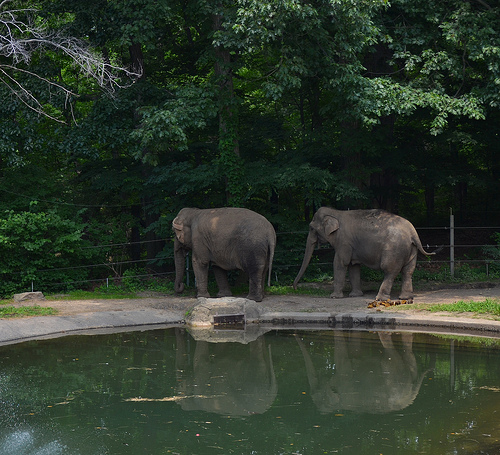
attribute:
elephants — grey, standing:
[169, 203, 437, 301]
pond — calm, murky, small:
[0, 322, 500, 454]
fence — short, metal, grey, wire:
[0, 223, 500, 290]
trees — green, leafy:
[1, 0, 498, 236]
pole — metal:
[447, 212, 458, 277]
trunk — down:
[172, 239, 188, 294]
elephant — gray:
[171, 205, 278, 302]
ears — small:
[320, 214, 339, 237]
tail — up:
[413, 228, 437, 257]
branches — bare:
[0, 1, 143, 129]